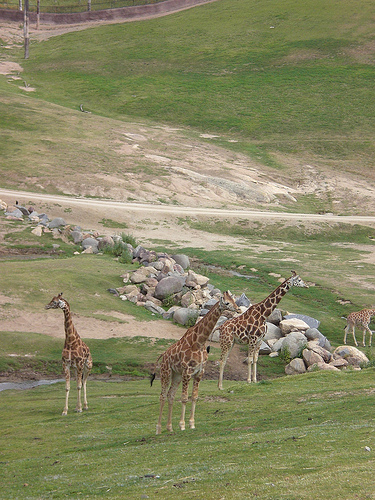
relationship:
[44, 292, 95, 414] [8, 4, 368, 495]
animal standing in green grass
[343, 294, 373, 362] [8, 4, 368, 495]
giraffe standing in green grass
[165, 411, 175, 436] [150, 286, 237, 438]
white leg of animal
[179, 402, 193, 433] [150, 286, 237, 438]
leg of animal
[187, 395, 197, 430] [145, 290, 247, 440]
leg of giraffe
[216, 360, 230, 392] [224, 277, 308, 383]
leg of giraffe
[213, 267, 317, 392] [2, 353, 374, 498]
animal standing on grass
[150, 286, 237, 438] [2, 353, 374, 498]
animal standing on grass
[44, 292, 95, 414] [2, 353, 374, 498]
animal standing on grass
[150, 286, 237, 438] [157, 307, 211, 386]
animal has spots